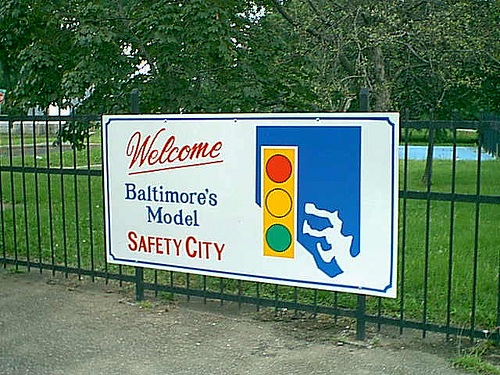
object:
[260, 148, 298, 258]
light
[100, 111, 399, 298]
sign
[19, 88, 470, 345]
fence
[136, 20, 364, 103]
tree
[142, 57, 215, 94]
leave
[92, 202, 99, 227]
grass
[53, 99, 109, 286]
bar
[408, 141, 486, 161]
pond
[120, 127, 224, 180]
word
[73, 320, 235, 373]
side walk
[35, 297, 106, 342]
ground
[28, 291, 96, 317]
cement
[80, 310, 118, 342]
path